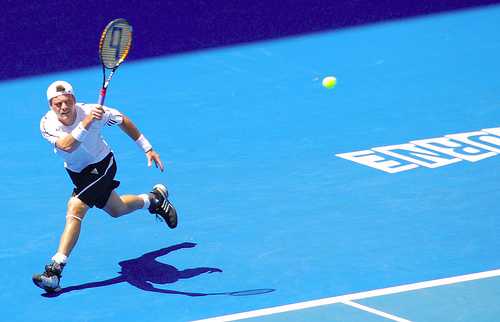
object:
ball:
[321, 76, 339, 88]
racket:
[95, 17, 133, 110]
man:
[32, 81, 178, 294]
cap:
[46, 79, 76, 102]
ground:
[0, 0, 499, 322]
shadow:
[44, 241, 277, 300]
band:
[135, 133, 154, 154]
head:
[47, 80, 75, 122]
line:
[346, 298, 411, 321]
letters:
[334, 147, 421, 174]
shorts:
[67, 152, 122, 208]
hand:
[88, 106, 105, 124]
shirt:
[39, 103, 123, 173]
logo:
[109, 26, 123, 60]